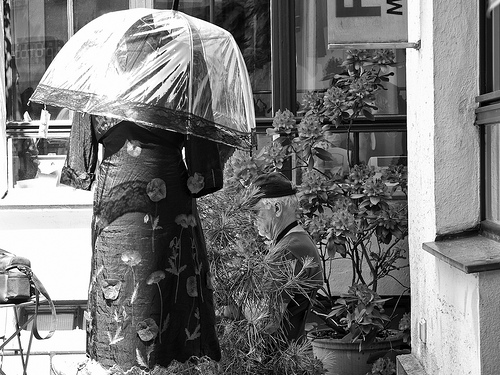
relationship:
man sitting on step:
[229, 173, 320, 368] [237, 307, 325, 369]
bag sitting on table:
[0, 255, 60, 355] [14, 237, 81, 335]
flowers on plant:
[292, 60, 390, 302] [286, 27, 410, 369]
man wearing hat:
[229, 173, 320, 368] [237, 151, 312, 241]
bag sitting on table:
[0, 255, 59, 343] [1, 299, 38, 374]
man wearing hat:
[229, 173, 320, 368] [241, 160, 308, 203]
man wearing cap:
[238, 173, 321, 340] [237, 172, 294, 209]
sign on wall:
[320, 4, 445, 57] [408, 286, 471, 354]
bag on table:
[0, 255, 59, 343] [0, 278, 45, 373]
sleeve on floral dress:
[56, 96, 98, 192] [56, 12, 246, 365]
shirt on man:
[261, 232, 325, 287] [229, 168, 324, 326]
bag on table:
[0, 255, 59, 343] [0, 296, 42, 373]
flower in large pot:
[314, 85, 356, 125] [316, 335, 375, 373]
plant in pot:
[292, 155, 402, 322] [304, 320, 409, 373]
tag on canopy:
[37, 105, 52, 145] [24, 7, 264, 154]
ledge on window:
[425, 208, 496, 291] [430, 1, 500, 268]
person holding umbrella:
[64, 17, 239, 369] [19, 6, 259, 161]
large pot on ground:
[311, 335, 377, 375] [7, 314, 120, 373]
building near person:
[395, 0, 499, 370] [224, 167, 326, 356]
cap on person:
[237, 172, 298, 207] [83, 115, 231, 370]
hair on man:
[256, 189, 298, 212] [229, 173, 320, 368]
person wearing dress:
[64, 17, 238, 370] [60, 93, 246, 373]